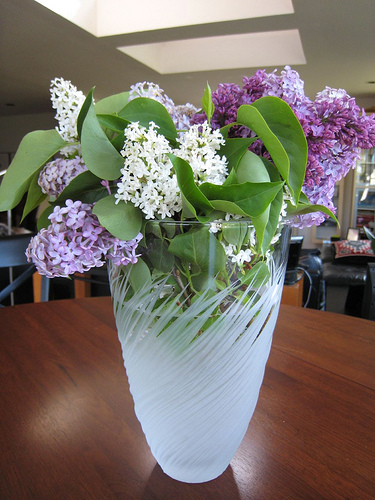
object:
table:
[0, 295, 374, 498]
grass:
[130, 278, 262, 376]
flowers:
[49, 74, 97, 140]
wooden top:
[0, 302, 374, 500]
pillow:
[328, 234, 372, 261]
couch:
[321, 237, 373, 310]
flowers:
[113, 117, 228, 223]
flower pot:
[105, 225, 290, 483]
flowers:
[37, 156, 88, 197]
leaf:
[0, 129, 65, 211]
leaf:
[76, 86, 124, 181]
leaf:
[116, 97, 178, 140]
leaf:
[91, 195, 143, 240]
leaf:
[234, 94, 307, 211]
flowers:
[26, 197, 145, 281]